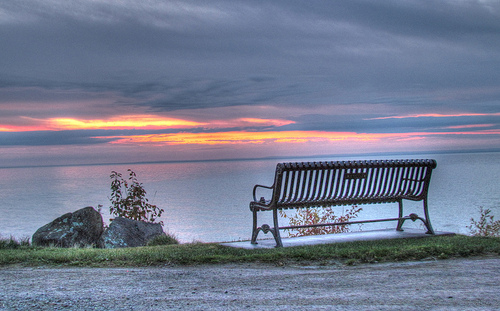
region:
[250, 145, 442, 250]
Bench facing the water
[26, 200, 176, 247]
Rocks next to the path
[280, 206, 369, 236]
Shrub in front of the bench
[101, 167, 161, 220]
Shrub in front of the rocks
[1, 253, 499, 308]
Pathway behind the bench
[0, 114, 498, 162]
Horizon above the water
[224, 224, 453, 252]
Platform beneath bench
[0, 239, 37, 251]
Grass next to rock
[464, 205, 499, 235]
Shrub to the right of bench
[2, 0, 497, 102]
Clouds above horizon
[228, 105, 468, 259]
bench facing the horizen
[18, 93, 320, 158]
glow of sun behind clouds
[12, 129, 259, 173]
horizen line glow of sun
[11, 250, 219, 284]
green plants along egde of road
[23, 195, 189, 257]
two rocks in front of plant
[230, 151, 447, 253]
bench on cement slab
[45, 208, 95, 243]
lichen on a rock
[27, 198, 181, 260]
two rocks with lichen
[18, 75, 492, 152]
clouds covering glow of sun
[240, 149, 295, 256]
side of metal bench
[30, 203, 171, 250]
large rocks with spots of moss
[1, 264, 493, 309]
a dirt and gravel path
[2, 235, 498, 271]
short green grass growing beside the path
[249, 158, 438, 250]
a metal bench facing towards water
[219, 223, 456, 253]
a cement slab holding the bench in place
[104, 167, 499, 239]
tree tops reaching for the sky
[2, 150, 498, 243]
a large body of calm water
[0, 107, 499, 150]
orange and pink clouds colored by the sun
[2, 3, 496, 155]
overcast sky covering the lake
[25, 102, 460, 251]
a picturesque seat gazing out over the water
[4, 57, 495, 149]
Orange sunset behing clouds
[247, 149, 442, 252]
Empty ornate steel bench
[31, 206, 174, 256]
two large grey and blue speckled rocks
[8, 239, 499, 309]
dirt ground with grass on edge of dirt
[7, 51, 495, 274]
empty bench overlooking sea and sunset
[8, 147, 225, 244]
calm blue sea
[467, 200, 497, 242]
small leaves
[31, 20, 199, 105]
dark clouds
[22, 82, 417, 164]
horizon between the sea and sunset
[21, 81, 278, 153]
sun peeking through the clouds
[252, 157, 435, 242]
A bench over-looking the water.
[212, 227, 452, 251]
A piece of cement below a bench.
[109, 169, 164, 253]
A small tree growing near some rocks.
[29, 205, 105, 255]
A rock with green moss growing on it.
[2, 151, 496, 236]
Blue ocean water.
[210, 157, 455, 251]
A bench on a cement slab.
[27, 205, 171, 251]
Two rocks with green moss.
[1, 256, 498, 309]
A dirt road over looking the ocean.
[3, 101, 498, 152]
The sun setting behind some clouds.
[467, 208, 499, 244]
A small bush growing beside the road.